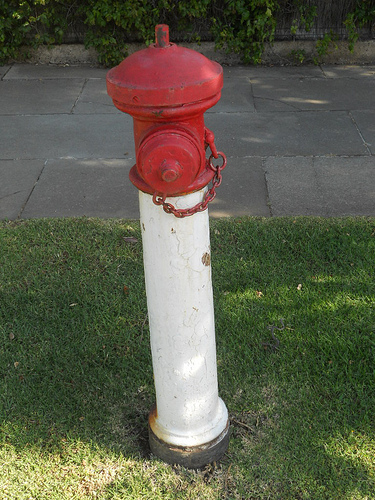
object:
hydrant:
[104, 26, 233, 474]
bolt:
[157, 158, 184, 183]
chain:
[154, 159, 229, 218]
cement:
[0, 40, 375, 219]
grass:
[1, 219, 375, 498]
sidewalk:
[0, 67, 375, 221]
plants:
[88, 4, 147, 56]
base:
[142, 399, 233, 467]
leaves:
[229, 1, 344, 31]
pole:
[136, 189, 220, 447]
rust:
[153, 25, 166, 52]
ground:
[1, 22, 374, 500]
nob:
[136, 129, 206, 196]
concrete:
[3, 35, 375, 216]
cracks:
[17, 156, 52, 230]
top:
[102, 22, 226, 116]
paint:
[107, 21, 224, 202]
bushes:
[2, 2, 373, 61]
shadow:
[1, 74, 375, 454]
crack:
[256, 154, 279, 223]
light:
[229, 285, 371, 315]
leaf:
[105, 33, 120, 48]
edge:
[202, 195, 215, 333]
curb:
[2, 33, 374, 72]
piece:
[16, 218, 30, 228]